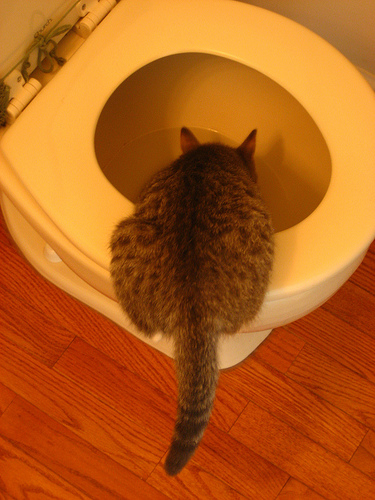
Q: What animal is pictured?
A: A cat.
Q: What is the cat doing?
A: Drinking from the toilet bowl.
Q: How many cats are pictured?
A: One.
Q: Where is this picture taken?
A: A bathroom.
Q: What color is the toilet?
A: White.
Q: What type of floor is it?
A: Wood.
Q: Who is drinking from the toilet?
A: The cat.